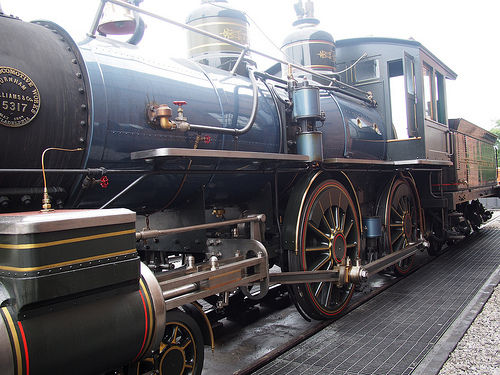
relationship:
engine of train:
[208, 47, 259, 71] [20, 65, 449, 258]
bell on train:
[147, 102, 193, 128] [20, 65, 449, 258]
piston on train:
[2, 251, 150, 335] [20, 65, 449, 258]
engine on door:
[208, 47, 259, 71] [370, 25, 427, 150]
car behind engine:
[432, 87, 491, 196] [208, 47, 259, 71]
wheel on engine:
[300, 183, 355, 309] [208, 47, 259, 71]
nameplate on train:
[5, 84, 40, 132] [20, 65, 449, 258]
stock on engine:
[257, 3, 337, 78] [208, 47, 259, 71]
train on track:
[20, 65, 449, 258] [258, 337, 286, 351]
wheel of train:
[300, 183, 355, 309] [20, 65, 449, 258]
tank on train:
[92, 0, 138, 35] [20, 65, 449, 258]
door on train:
[370, 25, 427, 150] [20, 65, 449, 258]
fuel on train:
[213, 68, 232, 76] [20, 65, 449, 258]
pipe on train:
[135, 12, 201, 37] [20, 65, 449, 258]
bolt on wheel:
[98, 165, 148, 191] [300, 183, 355, 309]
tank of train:
[92, 0, 138, 35] [20, 65, 449, 258]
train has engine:
[20, 65, 449, 258] [208, 47, 259, 71]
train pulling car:
[20, 65, 449, 258] [432, 87, 491, 196]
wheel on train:
[300, 183, 355, 309] [20, 65, 449, 258]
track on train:
[258, 337, 286, 351] [20, 65, 449, 258]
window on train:
[355, 58, 379, 88] [20, 65, 449, 258]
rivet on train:
[192, 211, 252, 250] [20, 65, 449, 258]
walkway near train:
[439, 304, 491, 357] [20, 65, 449, 258]